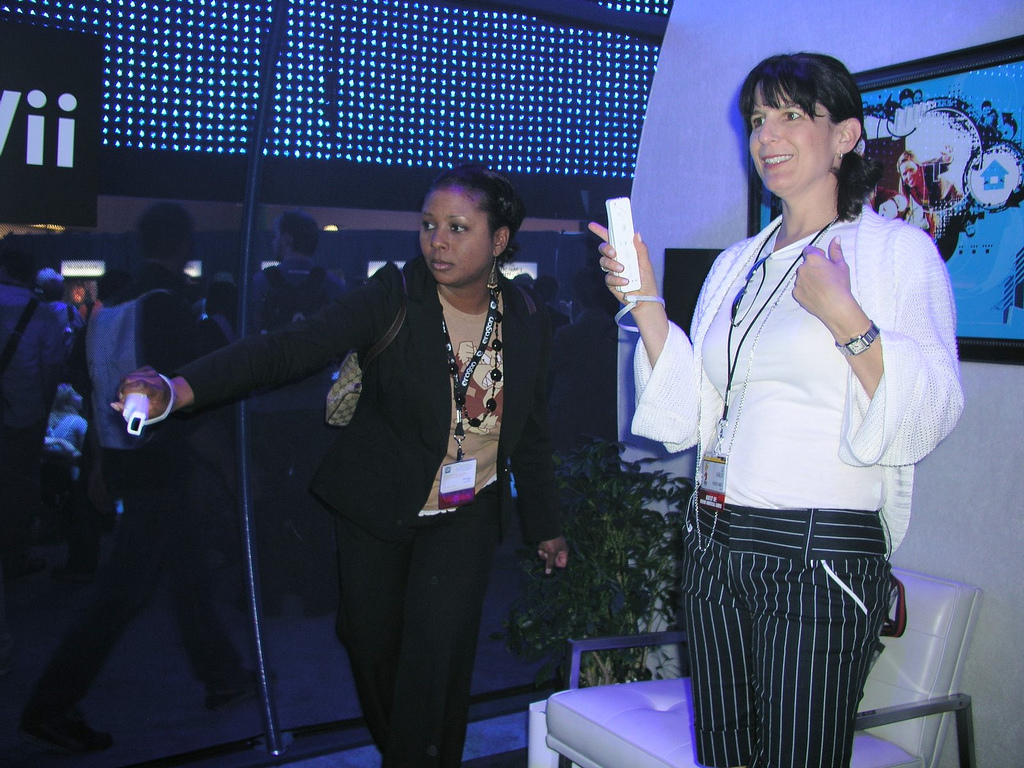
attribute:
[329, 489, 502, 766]
pants — black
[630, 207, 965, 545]
shirt — white